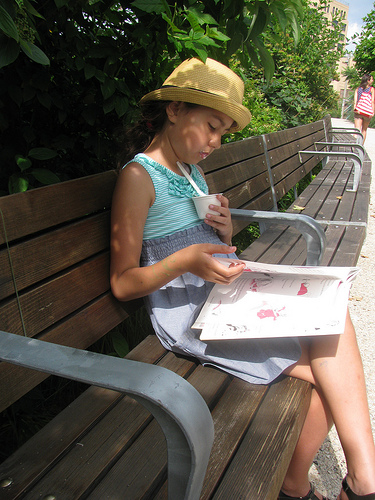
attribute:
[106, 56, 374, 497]
girl — sitting, reading, little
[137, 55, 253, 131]
hat — brown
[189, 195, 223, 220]
container — white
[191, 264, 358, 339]
book — open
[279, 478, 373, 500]
sandals — blue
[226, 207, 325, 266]
armrest — metal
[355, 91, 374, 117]
bag — striped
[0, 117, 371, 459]
benches — long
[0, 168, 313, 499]
bench — brown, long, wood, wooden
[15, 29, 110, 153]
leaves — green